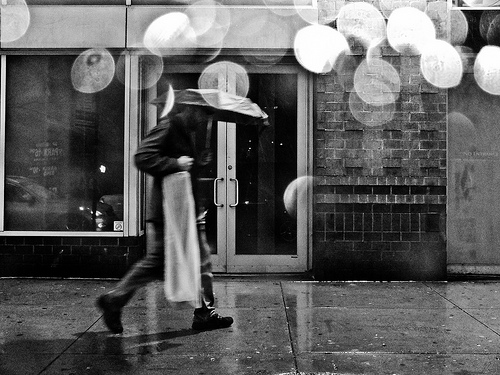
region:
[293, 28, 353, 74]
Circle mark made by a water drop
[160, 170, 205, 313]
Plastic bag held by a man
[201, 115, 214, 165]
Umbrella pole in a mans left hand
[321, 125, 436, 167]
Bricks in a wall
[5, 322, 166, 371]
Shadow of a walking man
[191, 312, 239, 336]
Man's shoe on the sidewalk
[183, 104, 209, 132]
Man with a beard on his face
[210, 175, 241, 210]
Metal handles on a glass door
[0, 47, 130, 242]
Glass window on a building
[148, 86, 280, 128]
Umbrella over a man's head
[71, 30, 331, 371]
person walking down street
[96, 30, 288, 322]
man with an umbrella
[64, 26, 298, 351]
the man has a garment bag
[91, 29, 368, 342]
the man walks past a doorway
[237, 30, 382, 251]
a brick wall and glass door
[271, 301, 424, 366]
the pavement is wet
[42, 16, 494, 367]
the photo is black and white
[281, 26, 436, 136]
these are reflected lights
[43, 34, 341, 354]
the man walks fast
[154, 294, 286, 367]
his shoe is black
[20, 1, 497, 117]
Water dropplet spots.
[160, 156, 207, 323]
A type of bag.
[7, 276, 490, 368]
a wet sidewalk.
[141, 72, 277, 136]
A dark umbrella.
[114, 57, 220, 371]
A man walking on the sidewalk, holding an umbrella and a bag.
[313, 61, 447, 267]
A brick wall on a building.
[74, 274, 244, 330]
A pair of dark shoes.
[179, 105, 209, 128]
A beard on the man's face.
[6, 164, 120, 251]
A refection of a car in the window.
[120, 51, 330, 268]
Double doors on the brick building.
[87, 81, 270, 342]
a man walking in the rain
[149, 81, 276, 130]
an open umbrella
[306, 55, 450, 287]
a patterned brick wall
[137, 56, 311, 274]
two glass building doors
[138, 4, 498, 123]
rain drops on the camera lens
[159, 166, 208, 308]
a white towel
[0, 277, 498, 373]
a wet paved sidewalk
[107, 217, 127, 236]
a no smoking sticker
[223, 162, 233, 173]
a keyhole for a door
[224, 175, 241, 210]
a door pull handle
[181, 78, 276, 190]
Person holding umbrella.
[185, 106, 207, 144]
Person has dark facial hair.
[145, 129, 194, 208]
Person wearing dark jacket.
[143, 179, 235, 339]
White towel hanging from side of person.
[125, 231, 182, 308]
Person wearing long pants.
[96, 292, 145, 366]
Person has dark shoes on.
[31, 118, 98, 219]
Large window on store.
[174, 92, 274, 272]
Glass double doors on building.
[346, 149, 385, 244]
Brick building near man walking.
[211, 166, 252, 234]
Silver door handles on doors.